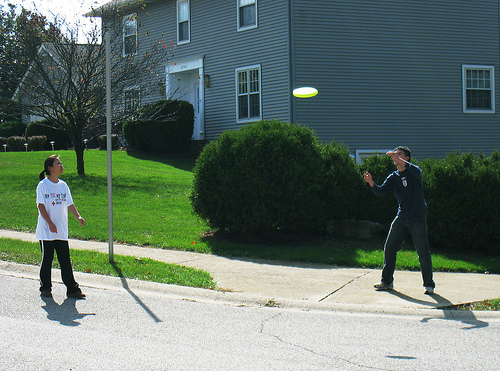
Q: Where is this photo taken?
A: On a street corner.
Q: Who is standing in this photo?
A: A man and woman.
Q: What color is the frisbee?
A: Yellow.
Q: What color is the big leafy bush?
A: Green.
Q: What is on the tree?
A: No leaves.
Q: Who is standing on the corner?
A: A man.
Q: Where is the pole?
A: Next to the sidewalk.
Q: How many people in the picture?
A: Two.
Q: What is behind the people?
A: A house.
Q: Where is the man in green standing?
A: On a sidewalk.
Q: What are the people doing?
A: Playing frisbee.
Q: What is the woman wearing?
A: A white T-shirt and black pants.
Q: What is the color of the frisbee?
A: Yellow.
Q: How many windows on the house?
A: Six.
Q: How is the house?
A: Large and grey colored.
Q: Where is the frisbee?
A: In the air.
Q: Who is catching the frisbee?
A: The man.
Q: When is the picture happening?
A: Daytime.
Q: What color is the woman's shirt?
A: White.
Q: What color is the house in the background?
A: Grey.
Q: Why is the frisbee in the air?
A: They are playing a game.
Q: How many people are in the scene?
A: 2.